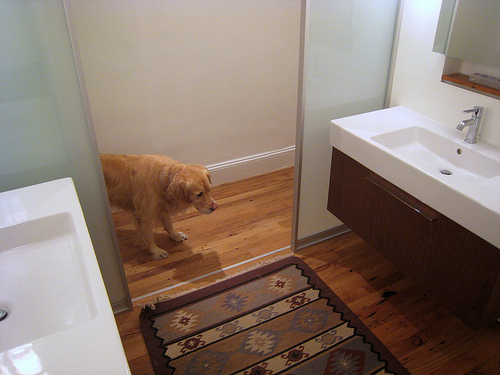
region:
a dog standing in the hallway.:
[96, 148, 226, 285]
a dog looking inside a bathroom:
[113, 135, 264, 237]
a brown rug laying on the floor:
[148, 285, 417, 368]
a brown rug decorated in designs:
[179, 310, 304, 371]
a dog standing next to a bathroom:
[95, 120, 304, 297]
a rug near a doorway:
[139, 303, 359, 373]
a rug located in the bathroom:
[144, 294, 448, 369]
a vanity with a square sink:
[358, 102, 499, 207]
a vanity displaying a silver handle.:
[361, 166, 441, 263]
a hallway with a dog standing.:
[80, 133, 272, 270]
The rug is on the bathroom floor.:
[135, 273, 397, 373]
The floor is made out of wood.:
[223, 181, 295, 259]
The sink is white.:
[329, 98, 499, 205]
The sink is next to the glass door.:
[303, 0, 497, 205]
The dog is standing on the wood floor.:
[97, 148, 244, 273]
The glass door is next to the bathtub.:
[0, 98, 122, 373]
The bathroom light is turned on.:
[404, 0, 448, 56]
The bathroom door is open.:
[69, 0, 326, 290]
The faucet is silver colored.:
[446, 91, 490, 155]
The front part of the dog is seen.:
[119, 152, 226, 272]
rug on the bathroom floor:
[203, 296, 334, 368]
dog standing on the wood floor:
[113, 153, 220, 258]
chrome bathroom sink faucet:
[456, 104, 485, 149]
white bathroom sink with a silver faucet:
[373, 110, 484, 172]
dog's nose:
[208, 201, 216, 209]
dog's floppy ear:
[166, 175, 191, 208]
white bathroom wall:
[397, 58, 429, 96]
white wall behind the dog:
[101, 6, 290, 142]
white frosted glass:
[312, 0, 387, 104]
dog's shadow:
[163, 241, 225, 282]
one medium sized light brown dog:
[101, 146, 219, 263]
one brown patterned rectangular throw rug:
[131, 245, 416, 374]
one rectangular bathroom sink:
[338, 88, 498, 248]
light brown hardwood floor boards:
[217, 188, 289, 245]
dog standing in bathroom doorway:
[65, 6, 318, 308]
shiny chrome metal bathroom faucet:
[451, 100, 485, 151]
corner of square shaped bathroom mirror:
[436, 21, 481, 98]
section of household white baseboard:
[213, 138, 295, 191]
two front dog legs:
[137, 218, 190, 263]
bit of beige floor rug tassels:
[138, 290, 172, 311]